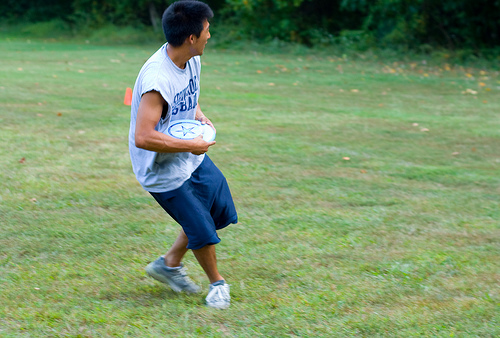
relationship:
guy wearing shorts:
[113, 1, 251, 315] [141, 146, 241, 256]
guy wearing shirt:
[113, 1, 251, 315] [120, 42, 209, 198]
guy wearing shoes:
[113, 1, 251, 315] [142, 254, 238, 315]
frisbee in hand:
[159, 118, 218, 154] [189, 132, 216, 158]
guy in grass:
[113, 1, 251, 315] [276, 128, 493, 297]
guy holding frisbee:
[113, 1, 251, 315] [159, 118, 218, 154]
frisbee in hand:
[159, 118, 218, 154] [197, 115, 217, 132]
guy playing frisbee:
[113, 1, 251, 315] [159, 118, 218, 154]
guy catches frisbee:
[113, 1, 251, 315] [159, 118, 218, 154]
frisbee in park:
[159, 118, 218, 154] [1, 1, 497, 337]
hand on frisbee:
[189, 132, 216, 158] [159, 118, 218, 154]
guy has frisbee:
[125, 1, 240, 312] [159, 118, 218, 154]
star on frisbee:
[173, 123, 198, 137] [159, 118, 218, 154]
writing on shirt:
[166, 74, 201, 116] [120, 42, 209, 198]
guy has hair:
[113, 1, 251, 315] [154, 0, 215, 49]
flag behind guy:
[119, 85, 136, 108] [113, 1, 251, 315]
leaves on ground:
[379, 58, 499, 103] [256, 56, 499, 184]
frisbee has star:
[159, 118, 218, 154] [173, 123, 198, 137]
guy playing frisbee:
[125, 1, 240, 312] [159, 118, 218, 154]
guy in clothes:
[113, 1, 251, 315] [125, 43, 241, 257]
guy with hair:
[113, 1, 251, 315] [154, 0, 215, 49]